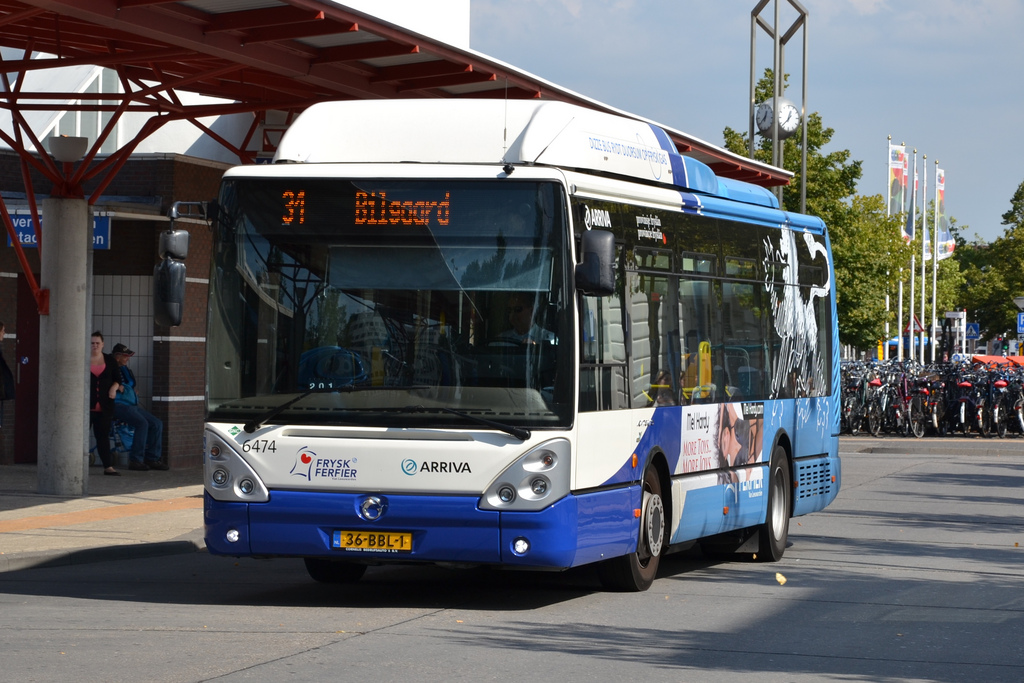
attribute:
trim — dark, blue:
[186, 432, 646, 575]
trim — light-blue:
[674, 158, 832, 232]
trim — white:
[521, 165, 688, 211]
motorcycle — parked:
[987, 355, 1013, 431]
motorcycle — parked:
[951, 357, 971, 424]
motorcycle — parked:
[944, 361, 975, 435]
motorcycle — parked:
[979, 346, 1012, 429]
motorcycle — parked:
[864, 363, 886, 430]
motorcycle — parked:
[948, 351, 974, 432]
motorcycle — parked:
[946, 350, 970, 441]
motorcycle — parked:
[944, 351, 971, 429]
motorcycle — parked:
[944, 346, 971, 424]